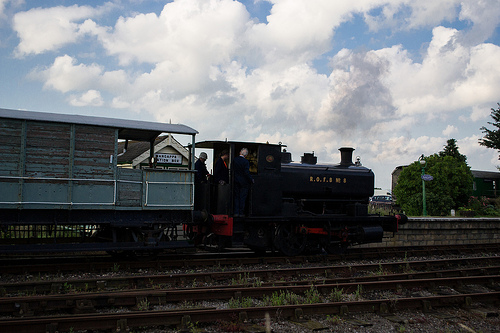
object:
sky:
[1, 0, 500, 194]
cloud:
[325, 46, 398, 124]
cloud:
[41, 55, 133, 110]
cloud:
[10, 3, 104, 56]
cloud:
[114, 0, 260, 66]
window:
[118, 126, 195, 171]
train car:
[0, 108, 197, 259]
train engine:
[180, 130, 410, 255]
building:
[119, 134, 200, 174]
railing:
[0, 173, 200, 206]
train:
[1, 105, 412, 260]